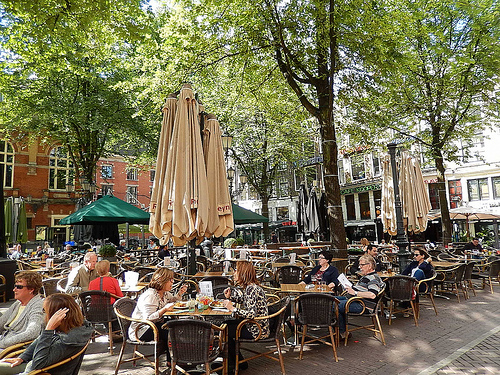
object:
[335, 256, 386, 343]
man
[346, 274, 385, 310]
shirt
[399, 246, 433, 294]
man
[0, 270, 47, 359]
man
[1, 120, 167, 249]
building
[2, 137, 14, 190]
window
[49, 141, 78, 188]
window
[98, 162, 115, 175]
window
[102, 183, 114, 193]
window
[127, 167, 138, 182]
window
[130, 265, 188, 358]
women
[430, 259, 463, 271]
table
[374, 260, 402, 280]
table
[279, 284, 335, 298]
table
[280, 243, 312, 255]
table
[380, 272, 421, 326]
chair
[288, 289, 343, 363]
chair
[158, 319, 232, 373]
chair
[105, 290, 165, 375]
chair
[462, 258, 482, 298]
chair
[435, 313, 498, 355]
ground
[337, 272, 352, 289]
menu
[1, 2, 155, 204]
tree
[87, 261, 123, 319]
person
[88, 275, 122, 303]
shirt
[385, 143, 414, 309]
metal pole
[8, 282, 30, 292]
sunglasses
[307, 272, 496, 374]
patio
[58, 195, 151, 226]
canopy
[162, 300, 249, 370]
table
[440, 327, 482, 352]
path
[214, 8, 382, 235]
tree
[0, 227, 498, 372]
dining area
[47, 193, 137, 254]
caffee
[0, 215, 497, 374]
cafe area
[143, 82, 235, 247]
canopy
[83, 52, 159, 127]
leaves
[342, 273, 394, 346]
chairs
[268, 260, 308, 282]
table